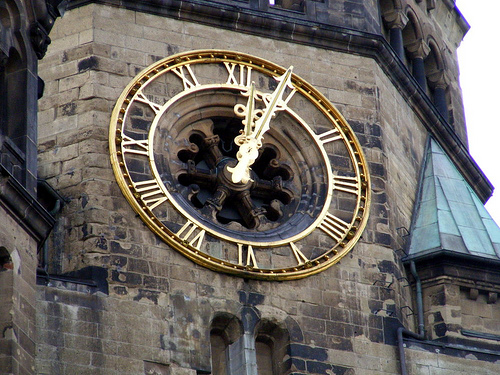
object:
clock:
[105, 47, 376, 284]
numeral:
[169, 63, 204, 92]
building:
[0, 0, 499, 375]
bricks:
[323, 85, 361, 108]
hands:
[233, 79, 264, 146]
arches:
[209, 307, 249, 375]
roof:
[401, 134, 500, 263]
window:
[252, 318, 291, 375]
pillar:
[393, 29, 407, 62]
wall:
[1, 204, 40, 374]